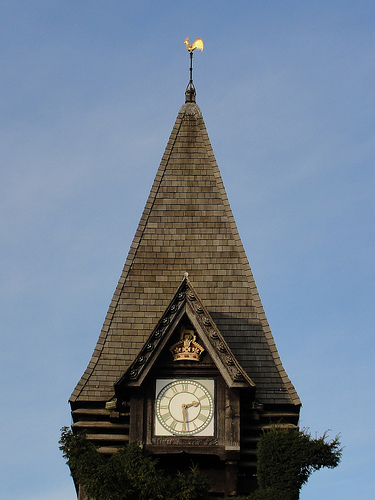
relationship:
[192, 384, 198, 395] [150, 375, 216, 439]
roman numeral on clock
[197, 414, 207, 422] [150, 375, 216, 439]
numeral on clock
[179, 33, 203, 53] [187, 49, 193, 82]
weather van on pole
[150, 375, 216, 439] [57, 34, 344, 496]
clock on tower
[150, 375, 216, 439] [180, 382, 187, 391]
clock has roman numeral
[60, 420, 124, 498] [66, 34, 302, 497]
trees in front of building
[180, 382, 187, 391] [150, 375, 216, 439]
roman numeral on clock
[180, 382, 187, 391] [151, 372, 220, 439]
roman numeral on clock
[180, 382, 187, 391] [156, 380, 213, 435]
roman numeral on clock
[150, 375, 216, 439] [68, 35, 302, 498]
clock on tower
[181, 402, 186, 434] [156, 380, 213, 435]
clock hand on clock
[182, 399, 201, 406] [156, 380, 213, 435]
clock hand on clock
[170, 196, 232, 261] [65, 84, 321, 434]
bricks on roof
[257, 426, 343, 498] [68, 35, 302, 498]
leaves on tower